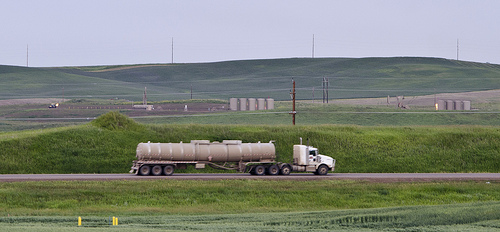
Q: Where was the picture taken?
A: It was taken at the field.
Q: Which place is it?
A: It is a field.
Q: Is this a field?
A: Yes, it is a field.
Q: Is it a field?
A: Yes, it is a field.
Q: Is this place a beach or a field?
A: It is a field.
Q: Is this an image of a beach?
A: No, the picture is showing a field.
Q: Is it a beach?
A: No, it is a field.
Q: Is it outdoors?
A: Yes, it is outdoors.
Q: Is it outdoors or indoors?
A: It is outdoors.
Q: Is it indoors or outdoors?
A: It is outdoors.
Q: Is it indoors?
A: No, it is outdoors.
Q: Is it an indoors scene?
A: No, it is outdoors.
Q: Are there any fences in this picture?
A: No, there are no fences.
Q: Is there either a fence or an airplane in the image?
A: No, there are no fences or airplanes.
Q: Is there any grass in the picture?
A: Yes, there is grass.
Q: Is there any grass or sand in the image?
A: Yes, there is grass.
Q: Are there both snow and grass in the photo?
A: No, there is grass but no snow.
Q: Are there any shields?
A: No, there are no shields.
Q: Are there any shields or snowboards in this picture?
A: No, there are no shields or snowboards.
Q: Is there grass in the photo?
A: Yes, there is grass.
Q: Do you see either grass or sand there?
A: Yes, there is grass.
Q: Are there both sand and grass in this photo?
A: No, there is grass but no sand.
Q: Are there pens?
A: No, there are no pens.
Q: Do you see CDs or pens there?
A: No, there are no pens or cds.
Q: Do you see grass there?
A: Yes, there is grass.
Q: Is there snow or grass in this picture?
A: Yes, there is grass.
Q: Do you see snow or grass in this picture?
A: Yes, there is grass.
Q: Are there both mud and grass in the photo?
A: No, there is grass but no mud.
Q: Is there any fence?
A: No, there are no fences.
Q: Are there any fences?
A: No, there are no fences.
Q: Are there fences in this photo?
A: No, there are no fences.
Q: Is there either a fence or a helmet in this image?
A: No, there are no fences or helmets.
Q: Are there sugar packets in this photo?
A: No, there are no sugar packets.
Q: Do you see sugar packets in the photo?
A: No, there are no sugar packets.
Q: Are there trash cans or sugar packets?
A: No, there are no sugar packets or trash cans.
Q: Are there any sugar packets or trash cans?
A: No, there are no sugar packets or trash cans.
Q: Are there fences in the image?
A: No, there are no fences.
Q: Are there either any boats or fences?
A: No, there are no fences or boats.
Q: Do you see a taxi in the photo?
A: Yes, there is a taxi.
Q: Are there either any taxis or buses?
A: Yes, there is a taxi.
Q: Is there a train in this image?
A: No, there are no trains.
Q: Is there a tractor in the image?
A: Yes, there is a tractor.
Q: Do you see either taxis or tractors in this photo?
A: Yes, there is a tractor.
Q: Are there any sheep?
A: No, there are no sheep.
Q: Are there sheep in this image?
A: No, there are no sheep.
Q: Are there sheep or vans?
A: No, there are no sheep or vans.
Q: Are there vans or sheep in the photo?
A: No, there are no sheep or vans.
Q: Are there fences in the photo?
A: No, there are no fences.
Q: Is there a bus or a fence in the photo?
A: No, there are no fences or buses.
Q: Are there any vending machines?
A: No, there are no vending machines.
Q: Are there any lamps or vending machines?
A: No, there are no vending machines or lamps.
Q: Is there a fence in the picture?
A: No, there are no fences.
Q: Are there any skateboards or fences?
A: No, there are no fences or skateboards.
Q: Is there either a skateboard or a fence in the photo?
A: No, there are no fences or skateboards.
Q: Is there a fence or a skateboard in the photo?
A: No, there are no fences or skateboards.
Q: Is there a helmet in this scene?
A: No, there are no helmets.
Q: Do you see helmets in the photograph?
A: No, there are no helmets.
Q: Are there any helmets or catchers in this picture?
A: No, there are no helmets or catchers.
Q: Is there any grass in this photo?
A: Yes, there is grass.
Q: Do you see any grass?
A: Yes, there is grass.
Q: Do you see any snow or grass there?
A: Yes, there is grass.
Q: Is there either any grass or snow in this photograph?
A: Yes, there is grass.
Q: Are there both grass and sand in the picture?
A: No, there is grass but no sand.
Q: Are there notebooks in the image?
A: No, there are no notebooks.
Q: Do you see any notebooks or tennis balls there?
A: No, there are no notebooks or tennis balls.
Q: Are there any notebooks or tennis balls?
A: No, there are no notebooks or tennis balls.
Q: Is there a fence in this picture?
A: No, there are no fences.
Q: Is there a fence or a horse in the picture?
A: No, there are no fences or horses.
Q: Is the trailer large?
A: Yes, the trailer is large.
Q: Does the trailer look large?
A: Yes, the trailer is large.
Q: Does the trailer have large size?
A: Yes, the trailer is large.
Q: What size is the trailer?
A: The trailer is large.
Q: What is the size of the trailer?
A: The trailer is large.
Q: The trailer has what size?
A: The trailer is large.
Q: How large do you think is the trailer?
A: The trailer is large.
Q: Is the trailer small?
A: No, the trailer is large.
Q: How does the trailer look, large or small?
A: The trailer is large.